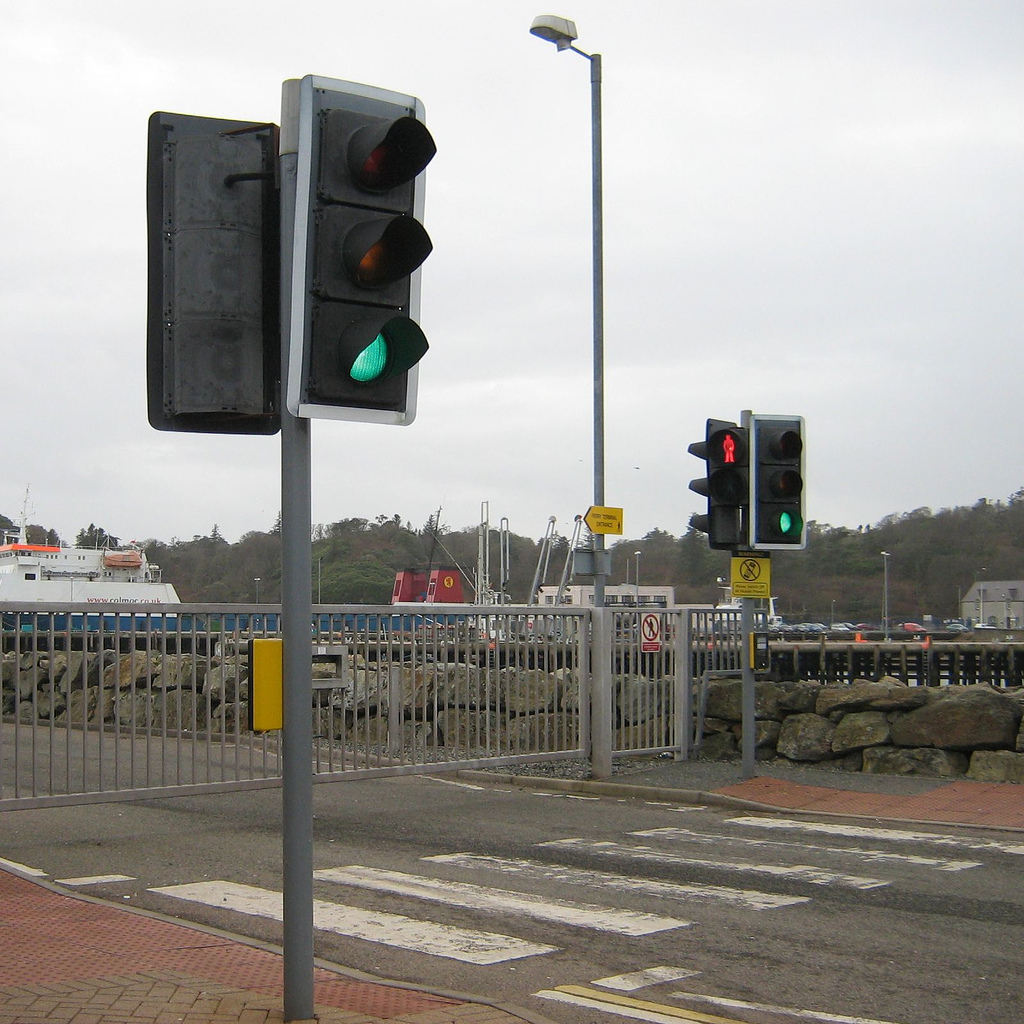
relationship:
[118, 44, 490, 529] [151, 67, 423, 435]
bank of a signal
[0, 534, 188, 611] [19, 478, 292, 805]
ship in background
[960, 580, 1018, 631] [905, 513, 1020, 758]
building off in distance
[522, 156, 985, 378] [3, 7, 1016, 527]
cloud cover in sky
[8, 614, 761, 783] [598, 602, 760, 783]
rails of a gate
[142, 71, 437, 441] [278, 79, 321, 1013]
traffic lights on pole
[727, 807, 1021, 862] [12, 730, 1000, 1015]
line on pavement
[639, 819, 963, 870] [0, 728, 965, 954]
line on pavement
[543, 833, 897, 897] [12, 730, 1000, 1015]
line on pavement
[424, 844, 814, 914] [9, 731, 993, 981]
line on pavement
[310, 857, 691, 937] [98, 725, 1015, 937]
line on pavement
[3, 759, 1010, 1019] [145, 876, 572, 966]
line on pavement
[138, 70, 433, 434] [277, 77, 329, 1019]
light on pole